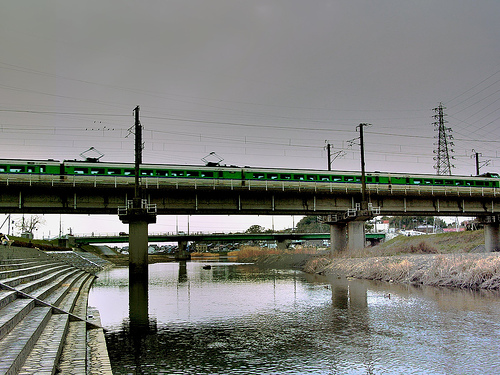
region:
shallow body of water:
[96, 253, 491, 374]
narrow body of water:
[96, 258, 496, 373]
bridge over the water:
[2, 150, 498, 283]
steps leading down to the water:
[0, 240, 127, 374]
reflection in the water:
[326, 275, 372, 313]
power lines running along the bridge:
[0, 92, 499, 174]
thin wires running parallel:
[435, 74, 499, 174]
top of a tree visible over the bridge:
[243, 220, 266, 235]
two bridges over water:
[1, 145, 498, 319]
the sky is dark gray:
[2, 1, 497, 178]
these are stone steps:
[6, 270, 118, 363]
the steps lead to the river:
[10, 279, 90, 368]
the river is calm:
[162, 263, 321, 366]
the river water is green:
[187, 289, 297, 370]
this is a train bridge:
[59, 120, 289, 216]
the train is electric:
[55, 110, 200, 187]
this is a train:
[131, 136, 386, 224]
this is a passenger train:
[155, 142, 362, 211]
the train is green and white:
[172, 146, 287, 210]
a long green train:
[1, 157, 497, 194]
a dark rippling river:
[96, 253, 498, 373]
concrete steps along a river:
[1, 243, 111, 374]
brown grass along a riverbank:
[311, 255, 497, 288]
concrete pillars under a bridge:
[128, 218, 148, 268]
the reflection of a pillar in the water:
[122, 278, 152, 340]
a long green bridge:
[71, 233, 386, 240]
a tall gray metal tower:
[430, 103, 455, 173]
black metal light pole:
[357, 124, 368, 189]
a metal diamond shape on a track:
[82, 144, 102, 161]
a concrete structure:
[5, 256, 96, 363]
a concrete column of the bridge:
[120, 209, 157, 339]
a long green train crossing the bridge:
[0, 160, 497, 187]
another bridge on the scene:
[72, 232, 384, 244]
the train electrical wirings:
[41, 108, 461, 155]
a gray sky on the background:
[48, 44, 453, 87]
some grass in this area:
[386, 233, 441, 251]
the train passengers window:
[75, 166, 134, 175]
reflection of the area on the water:
[200, 262, 291, 284]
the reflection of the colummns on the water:
[331, 272, 364, 311]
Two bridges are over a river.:
[1, 162, 498, 322]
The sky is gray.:
[1, 0, 498, 247]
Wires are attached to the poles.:
[2, 69, 498, 163]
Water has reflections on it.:
[91, 251, 499, 373]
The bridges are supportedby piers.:
[3, 173, 495, 281]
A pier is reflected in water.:
[117, 148, 157, 369]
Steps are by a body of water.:
[0, 247, 115, 373]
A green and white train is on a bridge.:
[0, 159, 497, 219]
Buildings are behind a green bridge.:
[86, 221, 470, 249]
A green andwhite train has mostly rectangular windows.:
[0, 159, 498, 186]